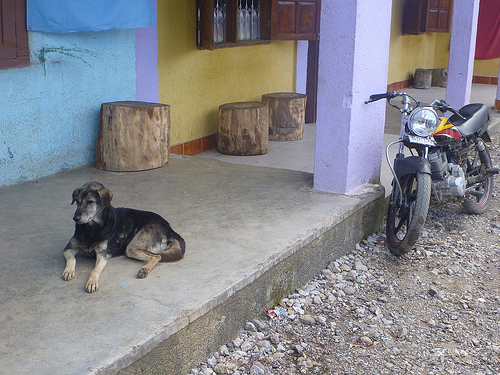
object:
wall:
[154, 0, 295, 148]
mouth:
[77, 217, 92, 225]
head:
[69, 181, 113, 225]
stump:
[214, 100, 271, 159]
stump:
[260, 91, 307, 140]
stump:
[99, 99, 171, 172]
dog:
[62, 181, 186, 293]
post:
[312, 0, 394, 193]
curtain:
[22, 0, 155, 34]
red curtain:
[475, 0, 500, 61]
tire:
[454, 138, 495, 214]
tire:
[385, 156, 431, 255]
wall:
[0, 29, 137, 185]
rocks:
[301, 314, 315, 323]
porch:
[0, 83, 500, 375]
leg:
[90, 250, 107, 277]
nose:
[71, 213, 80, 222]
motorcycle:
[364, 90, 500, 254]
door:
[304, 41, 320, 125]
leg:
[61, 237, 81, 270]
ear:
[96, 187, 113, 208]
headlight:
[407, 107, 440, 137]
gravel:
[360, 335, 372, 347]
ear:
[69, 188, 80, 205]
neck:
[85, 204, 116, 226]